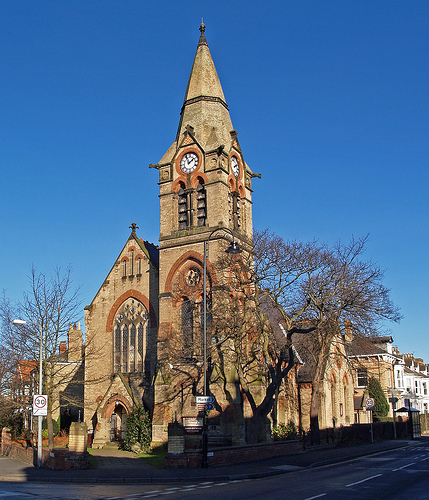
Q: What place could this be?
A: It is a church.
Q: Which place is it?
A: It is a church.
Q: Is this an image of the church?
A: Yes, it is showing the church.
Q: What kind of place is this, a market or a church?
A: It is a church.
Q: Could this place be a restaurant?
A: No, it is a church.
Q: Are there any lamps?
A: Yes, there is a lamp.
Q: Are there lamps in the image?
A: Yes, there is a lamp.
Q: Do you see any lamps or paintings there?
A: Yes, there is a lamp.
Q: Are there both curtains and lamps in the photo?
A: No, there is a lamp but no curtains.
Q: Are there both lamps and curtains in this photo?
A: No, there is a lamp but no curtains.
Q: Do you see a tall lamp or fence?
A: Yes, there is a tall lamp.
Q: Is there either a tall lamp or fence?
A: Yes, there is a tall lamp.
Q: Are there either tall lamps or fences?
A: Yes, there is a tall lamp.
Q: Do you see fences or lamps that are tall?
A: Yes, the lamp is tall.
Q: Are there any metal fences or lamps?
A: Yes, there is a metal lamp.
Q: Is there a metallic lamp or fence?
A: Yes, there is a metal lamp.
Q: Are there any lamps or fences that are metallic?
A: Yes, the lamp is metallic.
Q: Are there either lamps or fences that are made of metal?
A: Yes, the lamp is made of metal.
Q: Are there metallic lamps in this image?
A: Yes, there is a metal lamp.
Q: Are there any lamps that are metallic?
A: Yes, there is a lamp that is metallic.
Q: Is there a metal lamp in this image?
A: Yes, there is a lamp that is made of metal.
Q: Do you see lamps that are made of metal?
A: Yes, there is a lamp that is made of metal.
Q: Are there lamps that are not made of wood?
A: Yes, there is a lamp that is made of metal.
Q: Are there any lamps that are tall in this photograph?
A: Yes, there is a tall lamp.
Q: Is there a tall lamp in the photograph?
A: Yes, there is a tall lamp.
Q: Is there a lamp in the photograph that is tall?
A: Yes, there is a lamp that is tall.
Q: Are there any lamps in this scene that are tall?
A: Yes, there is a lamp that is tall.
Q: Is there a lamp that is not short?
A: Yes, there is a tall lamp.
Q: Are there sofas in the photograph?
A: No, there are no sofas.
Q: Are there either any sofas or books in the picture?
A: No, there are no sofas or books.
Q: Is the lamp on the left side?
A: Yes, the lamp is on the left of the image.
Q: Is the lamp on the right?
A: No, the lamp is on the left of the image.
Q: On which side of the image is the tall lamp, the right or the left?
A: The lamp is on the left of the image.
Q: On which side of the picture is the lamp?
A: The lamp is on the left of the image.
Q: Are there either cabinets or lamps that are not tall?
A: No, there is a lamp but it is tall.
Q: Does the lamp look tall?
A: Yes, the lamp is tall.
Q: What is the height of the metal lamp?
A: The lamp is tall.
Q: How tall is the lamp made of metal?
A: The lamp is tall.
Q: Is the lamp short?
A: No, the lamp is tall.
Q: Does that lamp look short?
A: No, the lamp is tall.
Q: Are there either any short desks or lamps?
A: No, there is a lamp but it is tall.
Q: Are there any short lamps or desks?
A: No, there is a lamp but it is tall.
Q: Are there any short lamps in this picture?
A: No, there is a lamp but it is tall.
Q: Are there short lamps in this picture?
A: No, there is a lamp but it is tall.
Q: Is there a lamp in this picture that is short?
A: No, there is a lamp but it is tall.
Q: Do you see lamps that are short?
A: No, there is a lamp but it is tall.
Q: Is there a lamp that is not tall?
A: No, there is a lamp but it is tall.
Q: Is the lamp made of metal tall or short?
A: The lamp is tall.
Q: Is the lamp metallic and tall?
A: Yes, the lamp is metallic and tall.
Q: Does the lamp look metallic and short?
A: No, the lamp is metallic but tall.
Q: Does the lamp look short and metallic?
A: No, the lamp is metallic but tall.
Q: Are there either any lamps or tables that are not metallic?
A: No, there is a lamp but it is metallic.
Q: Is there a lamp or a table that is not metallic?
A: No, there is a lamp but it is metallic.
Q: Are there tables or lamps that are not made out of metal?
A: No, there is a lamp but it is made of metal.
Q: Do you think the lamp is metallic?
A: Yes, the lamp is metallic.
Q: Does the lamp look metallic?
A: Yes, the lamp is metallic.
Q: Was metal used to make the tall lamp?
A: Yes, the lamp is made of metal.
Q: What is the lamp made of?
A: The lamp is made of metal.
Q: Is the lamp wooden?
A: No, the lamp is metallic.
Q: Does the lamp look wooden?
A: No, the lamp is metallic.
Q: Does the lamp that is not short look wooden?
A: No, the lamp is metallic.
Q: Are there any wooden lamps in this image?
A: No, there is a lamp but it is metallic.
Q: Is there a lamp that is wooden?
A: No, there is a lamp but it is metallic.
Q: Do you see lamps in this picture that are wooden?
A: No, there is a lamp but it is metallic.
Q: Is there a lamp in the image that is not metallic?
A: No, there is a lamp but it is metallic.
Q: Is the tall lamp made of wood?
A: No, the lamp is made of metal.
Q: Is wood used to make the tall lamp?
A: No, the lamp is made of metal.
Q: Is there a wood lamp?
A: No, there is a lamp but it is made of metal.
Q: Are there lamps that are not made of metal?
A: No, there is a lamp but it is made of metal.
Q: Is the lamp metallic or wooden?
A: The lamp is metallic.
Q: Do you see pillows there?
A: No, there are no pillows.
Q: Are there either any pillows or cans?
A: No, there are no pillows or cans.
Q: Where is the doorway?
A: The doorway is at the church.